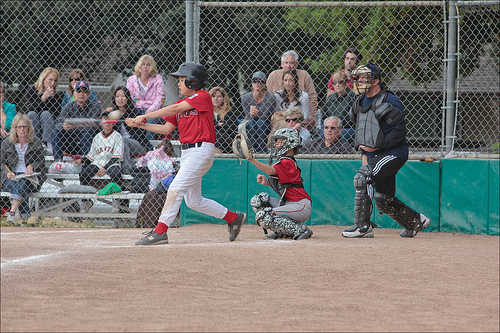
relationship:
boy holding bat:
[120, 56, 251, 253] [60, 105, 152, 141]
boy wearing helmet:
[120, 56, 251, 253] [166, 54, 216, 99]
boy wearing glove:
[226, 115, 328, 247] [229, 121, 260, 171]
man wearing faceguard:
[338, 45, 437, 247] [345, 58, 388, 104]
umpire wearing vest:
[338, 45, 437, 247] [349, 85, 397, 157]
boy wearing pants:
[120, 56, 251, 253] [152, 137, 234, 232]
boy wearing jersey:
[70, 104, 134, 229] [84, 126, 127, 169]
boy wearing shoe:
[120, 56, 251, 253] [131, 225, 176, 250]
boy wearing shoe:
[120, 56, 251, 253] [224, 200, 253, 248]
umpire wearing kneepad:
[338, 45, 437, 247] [350, 159, 378, 197]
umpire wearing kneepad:
[338, 45, 437, 247] [370, 183, 404, 219]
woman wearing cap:
[235, 64, 279, 154] [248, 66, 271, 95]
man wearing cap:
[49, 75, 110, 162] [67, 75, 94, 102]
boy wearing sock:
[120, 56, 251, 253] [217, 201, 242, 228]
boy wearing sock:
[120, 56, 251, 253] [150, 211, 175, 239]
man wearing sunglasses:
[49, 75, 110, 162] [72, 85, 92, 96]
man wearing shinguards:
[338, 45, 437, 247] [389, 201, 430, 235]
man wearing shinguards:
[338, 45, 437, 247] [348, 188, 379, 241]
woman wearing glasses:
[1, 108, 52, 232] [11, 121, 32, 133]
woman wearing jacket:
[119, 42, 170, 142] [121, 71, 168, 113]